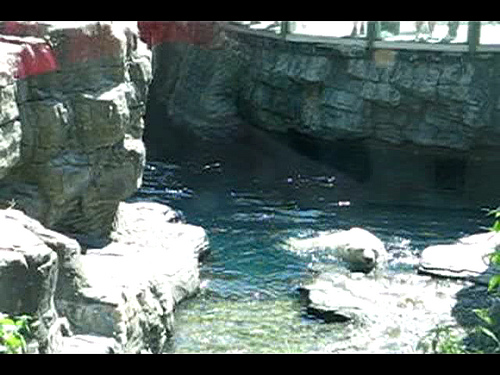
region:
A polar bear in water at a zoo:
[276, 217, 393, 277]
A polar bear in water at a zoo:
[276, 212, 390, 276]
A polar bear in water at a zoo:
[273, 212, 392, 282]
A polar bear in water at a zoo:
[285, 217, 383, 282]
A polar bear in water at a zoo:
[278, 217, 389, 282]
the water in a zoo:
[219, 184, 257, 224]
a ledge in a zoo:
[124, 216, 207, 286]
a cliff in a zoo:
[69, 90, 158, 187]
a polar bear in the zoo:
[280, 210, 395, 275]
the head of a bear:
[341, 230, 379, 273]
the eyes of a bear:
[351, 240, 385, 258]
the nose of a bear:
[366, 253, 378, 265]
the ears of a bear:
[335, 240, 359, 257]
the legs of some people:
[407, 19, 459, 44]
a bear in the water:
[295, 219, 399, 281]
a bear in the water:
[292, 202, 404, 296]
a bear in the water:
[297, 222, 402, 287]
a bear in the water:
[323, 222, 407, 282]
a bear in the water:
[320, 224, 413, 281]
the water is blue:
[202, 178, 269, 270]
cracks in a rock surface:
[30, 66, 123, 107]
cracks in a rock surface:
[39, 139, 125, 179]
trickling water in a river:
[166, 156, 331, 239]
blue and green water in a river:
[197, 244, 306, 351]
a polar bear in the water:
[282, 220, 397, 273]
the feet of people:
[343, 22, 465, 47]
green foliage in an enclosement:
[0, 307, 32, 358]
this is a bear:
[275, 200, 389, 299]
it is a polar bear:
[288, 202, 405, 290]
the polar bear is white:
[323, 197, 393, 302]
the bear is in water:
[240, 188, 427, 310]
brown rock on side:
[13, 43, 143, 188]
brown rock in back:
[167, 26, 489, 147]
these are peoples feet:
[375, 25, 469, 47]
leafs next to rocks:
[3, 287, 50, 354]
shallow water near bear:
[186, 285, 320, 345]